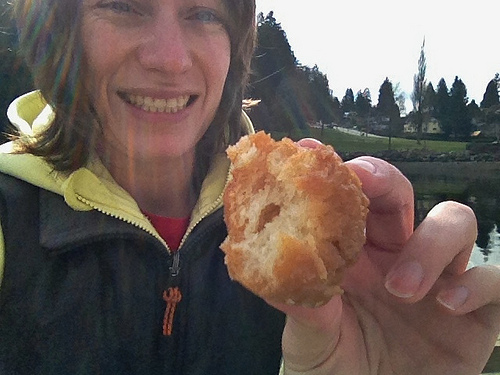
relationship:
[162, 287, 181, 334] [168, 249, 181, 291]
rope on zipper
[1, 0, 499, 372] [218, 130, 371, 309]
lady holding cake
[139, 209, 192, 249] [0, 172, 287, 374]
shirt under jacket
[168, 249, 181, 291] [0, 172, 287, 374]
zipper on jacket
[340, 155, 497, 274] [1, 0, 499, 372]
water behind lady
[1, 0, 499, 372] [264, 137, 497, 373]
lady has hand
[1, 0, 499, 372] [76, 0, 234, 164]
lady has face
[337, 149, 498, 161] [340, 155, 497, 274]
rocks line water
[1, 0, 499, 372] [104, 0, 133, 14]
lady has eye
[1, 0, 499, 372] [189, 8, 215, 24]
lady has eye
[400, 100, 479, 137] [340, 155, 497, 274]
house beyond water